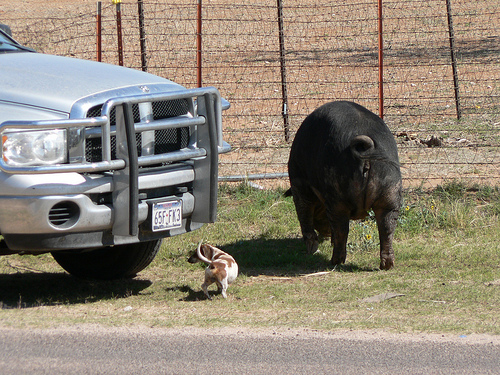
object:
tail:
[192, 237, 209, 264]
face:
[186, 241, 207, 262]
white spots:
[225, 261, 238, 283]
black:
[287, 98, 402, 272]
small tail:
[355, 133, 371, 161]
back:
[310, 100, 405, 232]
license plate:
[151, 207, 183, 232]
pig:
[275, 97, 406, 277]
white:
[230, 265, 237, 283]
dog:
[185, 238, 238, 301]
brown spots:
[197, 248, 233, 287]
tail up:
[188, 234, 215, 267]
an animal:
[283, 95, 405, 274]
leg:
[323, 217, 355, 273]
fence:
[8, 4, 498, 192]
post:
[273, 0, 291, 144]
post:
[371, 0, 385, 120]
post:
[444, 2, 465, 121]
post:
[195, 3, 203, 85]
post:
[113, 0, 125, 65]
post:
[94, 0, 103, 60]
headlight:
[0, 122, 68, 165]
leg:
[375, 193, 400, 270]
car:
[1, 24, 235, 298]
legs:
[332, 212, 355, 269]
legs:
[375, 209, 396, 273]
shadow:
[1, 264, 153, 318]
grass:
[5, 166, 497, 335]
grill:
[2, 89, 235, 174]